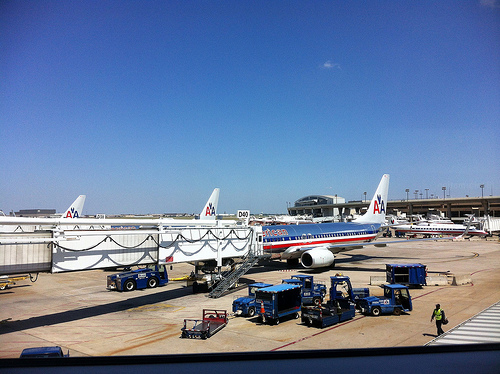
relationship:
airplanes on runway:
[48, 171, 394, 266] [5, 230, 499, 360]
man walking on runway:
[429, 301, 449, 336] [2, 272, 497, 362]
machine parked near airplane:
[105, 258, 167, 289] [259, 165, 408, 271]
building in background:
[282, 192, 495, 240] [6, 112, 499, 277]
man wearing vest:
[429, 301, 449, 336] [434, 310, 444, 322]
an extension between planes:
[3, 226, 256, 270] [118, 174, 399, 275]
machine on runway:
[105, 258, 167, 289] [2, 272, 497, 362]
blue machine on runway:
[254, 282, 302, 322] [2, 272, 497, 362]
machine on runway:
[293, 275, 327, 306] [2, 272, 497, 362]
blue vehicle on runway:
[298, 270, 353, 326] [2, 272, 497, 362]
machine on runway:
[356, 282, 412, 314] [2, 272, 497, 362]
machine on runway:
[179, 306, 231, 341] [2, 272, 497, 362]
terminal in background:
[284, 192, 498, 221] [2, 171, 498, 252]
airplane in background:
[392, 214, 469, 235] [3, 171, 498, 240]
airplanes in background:
[48, 171, 394, 266] [3, 171, 498, 240]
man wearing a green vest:
[429, 301, 449, 336] [433, 309, 443, 322]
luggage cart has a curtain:
[384, 261, 428, 288] [406, 266, 424, 281]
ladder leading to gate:
[206, 250, 263, 298] [2, 209, 257, 274]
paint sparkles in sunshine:
[265, 221, 384, 232] [5, 64, 498, 359]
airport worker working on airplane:
[430, 301, 449, 335] [392, 214, 469, 235]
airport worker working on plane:
[430, 301, 449, 335] [262, 171, 391, 270]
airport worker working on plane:
[430, 301, 449, 335] [198, 185, 219, 217]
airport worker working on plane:
[430, 301, 449, 335] [58, 191, 87, 221]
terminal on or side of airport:
[284, 192, 498, 221] [0, 191, 496, 369]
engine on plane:
[296, 247, 337, 272] [262, 171, 391, 270]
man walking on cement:
[429, 301, 449, 336] [0, 233, 497, 355]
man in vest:
[429, 301, 449, 336] [435, 309, 442, 320]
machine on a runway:
[179, 306, 231, 341] [2, 272, 497, 362]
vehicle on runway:
[230, 280, 274, 317] [2, 272, 497, 362]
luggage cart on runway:
[256, 280, 303, 322] [2, 272, 497, 362]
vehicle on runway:
[299, 272, 356, 327] [2, 272, 497, 362]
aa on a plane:
[65, 209, 80, 219] [58, 191, 88, 217]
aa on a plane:
[204, 204, 218, 216] [200, 185, 220, 219]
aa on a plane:
[371, 200, 388, 214] [262, 171, 391, 270]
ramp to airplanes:
[2, 209, 252, 278] [48, 171, 394, 266]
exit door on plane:
[256, 233, 265, 256] [256, 169, 396, 272]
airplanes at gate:
[48, 171, 394, 266] [2, 209, 257, 274]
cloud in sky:
[317, 51, 344, 77] [2, 2, 482, 219]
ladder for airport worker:
[206, 250, 263, 298] [430, 301, 449, 335]